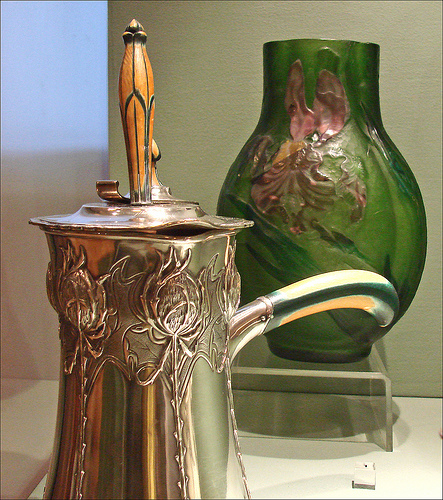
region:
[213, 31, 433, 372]
green and brown vase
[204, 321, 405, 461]
transparant display foundation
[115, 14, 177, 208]
wooden handle on long metal cannister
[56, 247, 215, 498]
floral metal design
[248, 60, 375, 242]
brown glass deign on green vase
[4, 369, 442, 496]
white display table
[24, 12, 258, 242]
metal and wood cannister top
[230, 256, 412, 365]
spout on side of metal cannister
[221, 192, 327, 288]
dark green lines on side of green vase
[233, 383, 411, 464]
shadow of vase on white table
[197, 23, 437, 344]
A vase sitting by the wall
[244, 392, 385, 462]
Shadow on the table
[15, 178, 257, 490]
Metal container in the front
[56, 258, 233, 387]
Design on the container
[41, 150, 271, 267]
Lid on the top of the container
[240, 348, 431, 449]
Clear shelf by the wall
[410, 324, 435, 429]
The wall is smooth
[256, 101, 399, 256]
The vase is see through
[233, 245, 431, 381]
Handle on the container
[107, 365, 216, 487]
Light reflecting on the container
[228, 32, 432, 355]
A green vase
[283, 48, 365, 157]
A pink flower on green vase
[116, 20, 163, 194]
Wooden handle on pt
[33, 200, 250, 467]
Gold colored decorative pot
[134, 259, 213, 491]
A flower design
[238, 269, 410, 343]
Curved handle on pot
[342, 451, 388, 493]
A plastic clip on counter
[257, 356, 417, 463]
A small metal or glass shelf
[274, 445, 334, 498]
A white counter top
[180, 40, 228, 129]
A light green wall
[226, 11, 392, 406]
the vase is green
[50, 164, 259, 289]
the lid is bronze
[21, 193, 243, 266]
the lid is bronze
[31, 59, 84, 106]
blue color on wall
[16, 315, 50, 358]
soft brown color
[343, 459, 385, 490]
white object on counter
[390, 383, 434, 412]
edge of green wall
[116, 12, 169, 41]
black and gold top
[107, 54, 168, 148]
gold surface with black lines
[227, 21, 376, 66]
edge of green ceramic glass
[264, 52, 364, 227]
pink flower design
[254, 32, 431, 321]
large green vase on surface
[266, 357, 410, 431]
large clear vase holder